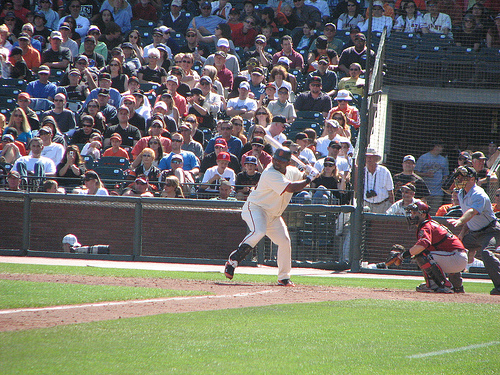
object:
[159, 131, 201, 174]
fan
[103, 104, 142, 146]
fan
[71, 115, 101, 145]
fan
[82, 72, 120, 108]
fan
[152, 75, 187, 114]
fan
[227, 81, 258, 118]
fan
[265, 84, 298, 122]
fan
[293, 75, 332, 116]
fan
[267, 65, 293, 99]
fan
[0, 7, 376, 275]
stand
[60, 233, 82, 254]
photographer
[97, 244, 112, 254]
lens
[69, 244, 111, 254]
camera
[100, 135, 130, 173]
fans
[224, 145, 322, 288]
batter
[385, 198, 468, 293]
catcher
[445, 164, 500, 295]
umpire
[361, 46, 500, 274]
netting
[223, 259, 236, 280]
foot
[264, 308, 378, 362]
grass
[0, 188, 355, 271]
fence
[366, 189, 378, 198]
camera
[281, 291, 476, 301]
dirt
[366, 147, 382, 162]
hat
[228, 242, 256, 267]
shin guard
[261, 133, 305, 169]
bat